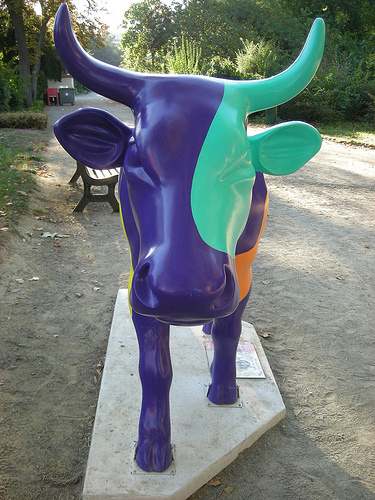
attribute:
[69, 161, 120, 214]
bench — wooden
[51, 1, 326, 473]
bull — painted, alone, multicolored, orange-colored, purple, aqua-colored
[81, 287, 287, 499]
foundation — white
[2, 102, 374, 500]
sand — brown, everywhere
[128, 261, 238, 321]
nose — purple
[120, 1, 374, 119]
trees — green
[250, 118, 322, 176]
left ear — teal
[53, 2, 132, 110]
right horn — purple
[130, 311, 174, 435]
leg — purple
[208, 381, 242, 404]
hoof — purple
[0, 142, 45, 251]
grass — green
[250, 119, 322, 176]
ear — teal